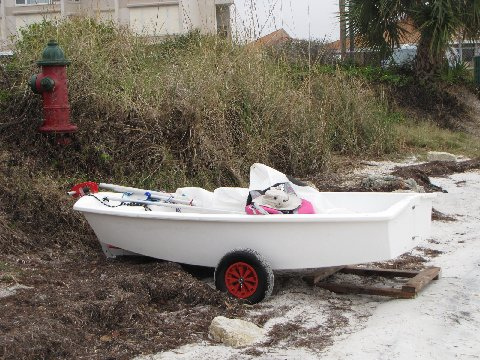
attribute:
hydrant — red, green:
[18, 48, 115, 141]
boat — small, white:
[66, 183, 443, 304]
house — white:
[3, 4, 237, 64]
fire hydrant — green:
[23, 35, 80, 148]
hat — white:
[244, 150, 312, 215]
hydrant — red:
[35, 30, 87, 134]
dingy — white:
[61, 166, 449, 307]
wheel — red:
[210, 247, 275, 307]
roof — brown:
[247, 28, 295, 57]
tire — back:
[207, 246, 279, 307]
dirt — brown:
[7, 232, 200, 347]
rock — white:
[212, 313, 261, 351]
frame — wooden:
[299, 260, 440, 299]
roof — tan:
[246, 29, 289, 53]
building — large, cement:
[71, 4, 162, 36]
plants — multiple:
[349, 65, 405, 107]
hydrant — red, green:
[27, 41, 81, 137]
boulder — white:
[203, 308, 276, 349]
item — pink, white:
[232, 159, 322, 221]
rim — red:
[220, 262, 260, 295]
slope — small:
[7, 39, 466, 197]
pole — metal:
[96, 180, 208, 206]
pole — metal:
[103, 193, 208, 213]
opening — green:
[26, 75, 37, 95]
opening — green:
[38, 74, 53, 93]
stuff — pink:
[244, 198, 313, 217]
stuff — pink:
[247, 194, 317, 214]